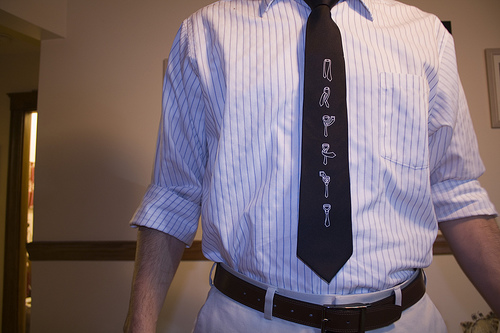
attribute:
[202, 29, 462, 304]
man — standing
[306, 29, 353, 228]
tie — black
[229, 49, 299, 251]
shirt — blue, striped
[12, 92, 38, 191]
door — open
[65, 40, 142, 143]
wall — dark, brown, white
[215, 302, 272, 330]
pants — brown